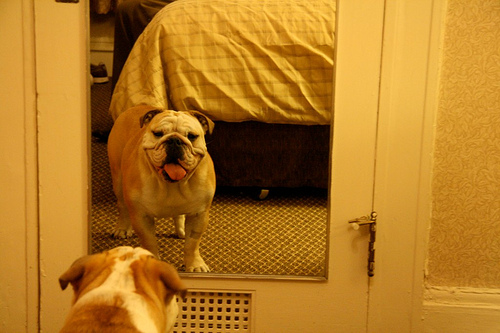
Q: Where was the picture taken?
A: It was taken at the bedroom.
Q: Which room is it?
A: It is a bedroom.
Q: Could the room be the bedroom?
A: Yes, it is the bedroom.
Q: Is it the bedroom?
A: Yes, it is the bedroom.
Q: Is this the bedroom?
A: Yes, it is the bedroom.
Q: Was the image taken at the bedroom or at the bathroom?
A: It was taken at the bedroom.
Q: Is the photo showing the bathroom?
A: No, the picture is showing the bedroom.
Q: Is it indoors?
A: Yes, it is indoors.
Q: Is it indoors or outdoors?
A: It is indoors.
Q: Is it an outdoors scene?
A: No, it is indoors.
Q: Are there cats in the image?
A: No, there are no cats.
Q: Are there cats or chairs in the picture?
A: No, there are no cats or chairs.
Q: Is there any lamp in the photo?
A: No, there are no lamps.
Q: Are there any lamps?
A: No, there are no lamps.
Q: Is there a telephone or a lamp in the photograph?
A: No, there are no lamps or phones.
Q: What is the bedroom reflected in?
A: The bedroom is reflected in the mirror.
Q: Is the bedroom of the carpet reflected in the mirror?
A: Yes, the bedroom is reflected in the mirror.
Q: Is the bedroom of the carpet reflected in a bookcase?
A: No, the bedroom is reflected in the mirror.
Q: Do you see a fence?
A: No, there are no fences.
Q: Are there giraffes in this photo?
A: No, there are no giraffes.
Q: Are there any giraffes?
A: No, there are no giraffes.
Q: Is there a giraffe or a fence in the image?
A: No, there are no giraffes or fences.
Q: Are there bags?
A: No, there are no bags.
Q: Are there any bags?
A: No, there are no bags.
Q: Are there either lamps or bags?
A: No, there are no bags or lamps.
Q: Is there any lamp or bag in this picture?
A: No, there are no bags or lamps.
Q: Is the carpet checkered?
A: Yes, the carpet is checkered.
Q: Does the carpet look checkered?
A: Yes, the carpet is checkered.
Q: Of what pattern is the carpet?
A: The carpet is checkered.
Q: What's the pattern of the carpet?
A: The carpet is checkered.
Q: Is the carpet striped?
A: No, the carpet is checkered.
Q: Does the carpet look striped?
A: No, the carpet is checkered.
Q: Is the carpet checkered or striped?
A: The carpet is checkered.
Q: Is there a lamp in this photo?
A: No, there are no lamps.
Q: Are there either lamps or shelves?
A: No, there are no lamps or shelves.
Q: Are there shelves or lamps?
A: No, there are no lamps or shelves.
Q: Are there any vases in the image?
A: No, there are no vases.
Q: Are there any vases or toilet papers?
A: No, there are no vases or toilet papers.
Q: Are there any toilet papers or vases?
A: No, there are no vases or toilet papers.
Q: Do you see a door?
A: Yes, there is a door.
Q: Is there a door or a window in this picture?
A: Yes, there is a door.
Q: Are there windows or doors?
A: Yes, there is a door.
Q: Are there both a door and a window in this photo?
A: No, there is a door but no windows.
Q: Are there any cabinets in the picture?
A: No, there are no cabinets.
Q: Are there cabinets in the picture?
A: No, there are no cabinets.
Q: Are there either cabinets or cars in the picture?
A: No, there are no cabinets or cars.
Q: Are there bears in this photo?
A: No, there are no bears.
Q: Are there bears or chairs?
A: No, there are no bears or chairs.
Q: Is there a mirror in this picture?
A: Yes, there is a mirror.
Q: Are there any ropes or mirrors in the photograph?
A: Yes, there is a mirror.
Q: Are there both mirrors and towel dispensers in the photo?
A: No, there is a mirror but no towel dispensers.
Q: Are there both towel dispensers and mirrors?
A: No, there is a mirror but no towel dispensers.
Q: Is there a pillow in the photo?
A: No, there are no pillows.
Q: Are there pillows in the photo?
A: No, there are no pillows.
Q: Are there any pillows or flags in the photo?
A: No, there are no pillows or flags.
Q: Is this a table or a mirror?
A: This is a mirror.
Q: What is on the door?
A: The mirror is on the door.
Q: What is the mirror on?
A: The mirror is on the door.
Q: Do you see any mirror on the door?
A: Yes, there is a mirror on the door.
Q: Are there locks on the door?
A: No, there is a mirror on the door.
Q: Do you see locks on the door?
A: No, there is a mirror on the door.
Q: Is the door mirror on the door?
A: Yes, the mirror is on the door.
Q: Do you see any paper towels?
A: No, there are no paper towels.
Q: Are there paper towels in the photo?
A: No, there are no paper towels.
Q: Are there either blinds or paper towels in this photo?
A: No, there are no paper towels or blinds.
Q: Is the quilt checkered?
A: Yes, the quilt is checkered.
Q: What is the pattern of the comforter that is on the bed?
A: The quilt is checkered.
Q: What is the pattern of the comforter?
A: The quilt is checkered.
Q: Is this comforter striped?
A: No, the comforter is checkered.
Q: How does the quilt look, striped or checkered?
A: The quilt is checkered.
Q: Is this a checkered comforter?
A: Yes, this is a checkered comforter.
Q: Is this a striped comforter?
A: No, this is a checkered comforter.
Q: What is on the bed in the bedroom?
A: The quilt is on the bed.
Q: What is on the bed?
A: The quilt is on the bed.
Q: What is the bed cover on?
A: The bed cover is on the bed.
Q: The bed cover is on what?
A: The bed cover is on the bed.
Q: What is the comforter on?
A: The bed cover is on the bed.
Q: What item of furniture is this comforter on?
A: The comforter is on the bed.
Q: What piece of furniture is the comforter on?
A: The comforter is on the bed.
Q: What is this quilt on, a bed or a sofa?
A: The quilt is on a bed.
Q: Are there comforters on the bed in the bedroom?
A: Yes, there is a comforter on the bed.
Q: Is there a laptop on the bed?
A: No, there is a comforter on the bed.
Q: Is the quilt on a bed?
A: Yes, the quilt is on a bed.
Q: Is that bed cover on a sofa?
A: No, the bed cover is on a bed.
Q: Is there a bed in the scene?
A: Yes, there is a bed.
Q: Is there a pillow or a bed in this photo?
A: Yes, there is a bed.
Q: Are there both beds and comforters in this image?
A: Yes, there are both a bed and a comforter.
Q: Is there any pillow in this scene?
A: No, there are no pillows.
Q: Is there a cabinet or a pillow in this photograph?
A: No, there are no pillows or cabinets.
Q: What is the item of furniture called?
A: The piece of furniture is a bed.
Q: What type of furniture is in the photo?
A: The furniture is a bed.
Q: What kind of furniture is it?
A: The piece of furniture is a bed.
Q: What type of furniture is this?
A: This is a bed.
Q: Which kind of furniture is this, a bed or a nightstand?
A: This is a bed.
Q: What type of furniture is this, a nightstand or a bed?
A: This is a bed.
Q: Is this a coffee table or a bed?
A: This is a bed.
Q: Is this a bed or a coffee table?
A: This is a bed.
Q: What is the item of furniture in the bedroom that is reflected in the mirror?
A: The piece of furniture is a bed.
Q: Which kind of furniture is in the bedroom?
A: The piece of furniture is a bed.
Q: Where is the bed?
A: The bed is in the bedroom.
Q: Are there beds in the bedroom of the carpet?
A: Yes, there is a bed in the bedroom.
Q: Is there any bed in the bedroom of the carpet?
A: Yes, there is a bed in the bedroom.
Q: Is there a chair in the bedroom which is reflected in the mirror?
A: No, there is a bed in the bedroom.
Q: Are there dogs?
A: Yes, there is a dog.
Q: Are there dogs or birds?
A: Yes, there is a dog.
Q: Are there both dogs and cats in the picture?
A: No, there is a dog but no cats.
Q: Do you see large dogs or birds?
A: Yes, there is a large dog.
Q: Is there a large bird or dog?
A: Yes, there is a large dog.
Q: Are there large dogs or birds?
A: Yes, there is a large dog.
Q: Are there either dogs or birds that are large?
A: Yes, the dog is large.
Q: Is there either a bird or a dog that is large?
A: Yes, the dog is large.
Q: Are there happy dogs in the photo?
A: Yes, there is a happy dog.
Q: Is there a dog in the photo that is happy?
A: Yes, there is a dog that is happy.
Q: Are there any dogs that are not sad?
A: Yes, there is a happy dog.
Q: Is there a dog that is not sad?
A: Yes, there is a happy dog.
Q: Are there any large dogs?
A: Yes, there is a large dog.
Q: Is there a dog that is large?
A: Yes, there is a dog that is large.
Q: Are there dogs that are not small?
A: Yes, there is a large dog.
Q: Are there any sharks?
A: No, there are no sharks.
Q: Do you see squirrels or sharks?
A: No, there are no sharks or squirrels.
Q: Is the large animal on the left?
A: Yes, the dog is on the left of the image.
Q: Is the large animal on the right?
A: No, the dog is on the left of the image.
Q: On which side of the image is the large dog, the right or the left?
A: The dog is on the left of the image.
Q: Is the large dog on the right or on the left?
A: The dog is on the left of the image.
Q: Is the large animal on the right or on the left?
A: The dog is on the left of the image.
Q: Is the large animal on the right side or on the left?
A: The dog is on the left of the image.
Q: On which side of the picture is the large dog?
A: The dog is on the left of the image.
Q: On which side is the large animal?
A: The dog is on the left of the image.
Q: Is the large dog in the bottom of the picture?
A: Yes, the dog is in the bottom of the image.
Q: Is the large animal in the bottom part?
A: Yes, the dog is in the bottom of the image.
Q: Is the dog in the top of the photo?
A: No, the dog is in the bottom of the image.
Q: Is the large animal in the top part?
A: No, the dog is in the bottom of the image.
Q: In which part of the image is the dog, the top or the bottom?
A: The dog is in the bottom of the image.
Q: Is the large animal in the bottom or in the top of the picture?
A: The dog is in the bottom of the image.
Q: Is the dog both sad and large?
A: No, the dog is large but happy.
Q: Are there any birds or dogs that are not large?
A: No, there is a dog but it is large.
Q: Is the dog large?
A: Yes, the dog is large.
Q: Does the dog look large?
A: Yes, the dog is large.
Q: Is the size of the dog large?
A: Yes, the dog is large.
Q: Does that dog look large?
A: Yes, the dog is large.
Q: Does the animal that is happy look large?
A: Yes, the dog is large.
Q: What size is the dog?
A: The dog is large.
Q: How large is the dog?
A: The dog is large.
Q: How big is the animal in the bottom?
A: The dog is large.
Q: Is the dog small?
A: No, the dog is large.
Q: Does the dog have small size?
A: No, the dog is large.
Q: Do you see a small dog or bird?
A: No, there is a dog but it is large.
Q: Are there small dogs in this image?
A: No, there is a dog but it is large.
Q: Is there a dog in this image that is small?
A: No, there is a dog but it is large.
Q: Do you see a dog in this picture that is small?
A: No, there is a dog but it is large.